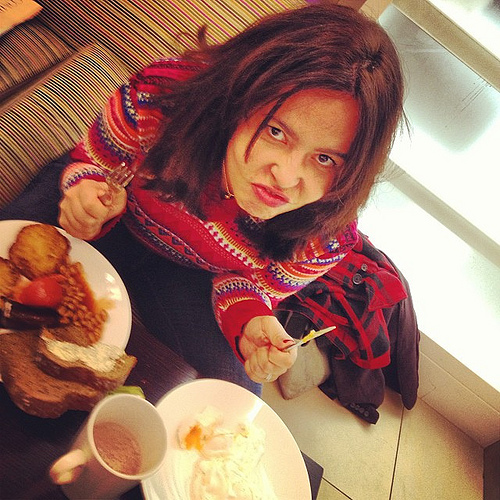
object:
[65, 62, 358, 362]
sweater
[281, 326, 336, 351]
knife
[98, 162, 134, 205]
fork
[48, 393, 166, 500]
mug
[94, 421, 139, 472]
cocoa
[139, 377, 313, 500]
plate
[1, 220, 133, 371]
plate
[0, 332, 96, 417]
toast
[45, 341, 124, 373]
butter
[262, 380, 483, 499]
floor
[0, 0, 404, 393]
woman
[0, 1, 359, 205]
couch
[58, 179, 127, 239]
hand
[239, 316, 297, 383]
hand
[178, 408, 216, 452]
eggs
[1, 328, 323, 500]
table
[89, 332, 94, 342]
beans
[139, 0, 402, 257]
hair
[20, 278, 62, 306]
tomato